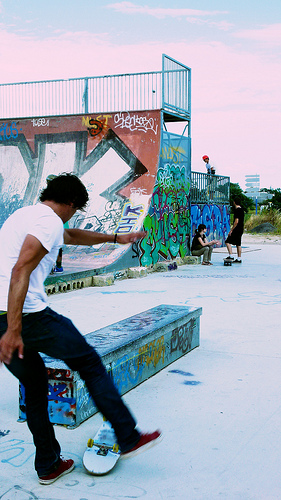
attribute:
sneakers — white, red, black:
[27, 429, 165, 484]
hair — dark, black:
[40, 172, 95, 209]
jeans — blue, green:
[3, 313, 139, 468]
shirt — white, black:
[1, 203, 65, 313]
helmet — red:
[202, 154, 209, 160]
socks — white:
[226, 255, 244, 261]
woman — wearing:
[204, 261, 215, 265]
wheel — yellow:
[85, 440, 118, 454]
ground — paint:
[10, 225, 276, 498]